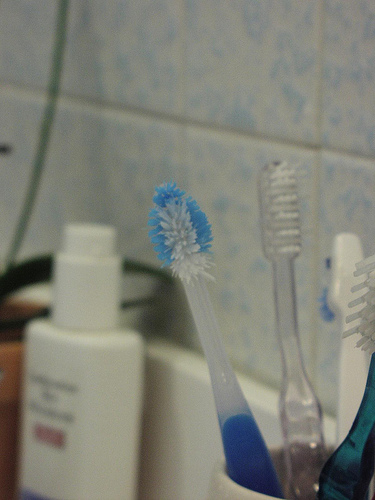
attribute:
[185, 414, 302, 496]
brush — blue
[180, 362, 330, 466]
brush — blue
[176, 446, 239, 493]
cup — white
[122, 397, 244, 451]
board — white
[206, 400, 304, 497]
brush — blue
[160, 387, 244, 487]
wall — white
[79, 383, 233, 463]
board — white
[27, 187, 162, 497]
bottle — white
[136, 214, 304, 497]
brush — white, blue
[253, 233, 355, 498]
brush — clear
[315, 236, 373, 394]
brush — white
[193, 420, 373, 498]
cup — white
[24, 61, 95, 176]
plant — green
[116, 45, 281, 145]
tiles — green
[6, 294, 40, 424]
pot — brown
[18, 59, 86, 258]
plant — green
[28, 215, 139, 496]
lotion — white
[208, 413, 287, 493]
handle — blue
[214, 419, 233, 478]
edge — blue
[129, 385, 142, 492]
edge — white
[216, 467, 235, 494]
edge — white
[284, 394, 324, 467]
handle — clear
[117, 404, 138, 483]
bottle — white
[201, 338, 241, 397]
handle — white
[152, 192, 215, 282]
bristles — white, blue, worn out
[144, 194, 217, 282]
bristles — white, blue, worn out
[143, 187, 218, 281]
bristles — white, blue, worn out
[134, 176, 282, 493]
toothbrush — used, white, blue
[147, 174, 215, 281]
bristles — blue, worn out, white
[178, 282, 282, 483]
handle — white, blue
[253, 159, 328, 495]
toothbrush — clear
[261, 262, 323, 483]
handle — clear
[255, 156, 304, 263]
bristles — white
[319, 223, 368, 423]
toothbrush — white, blue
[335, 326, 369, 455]
handle — white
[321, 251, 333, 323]
bristles — white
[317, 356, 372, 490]
toothbrush — transparent blue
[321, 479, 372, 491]
handle — transparent blue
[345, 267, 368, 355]
bristles — white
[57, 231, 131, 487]
bottle — white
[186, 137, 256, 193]
tile — white, blue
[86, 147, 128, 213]
tile — blue, white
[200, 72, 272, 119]
tile — white, blue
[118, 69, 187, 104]
tile — blue, white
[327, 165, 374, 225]
tile — white, blue